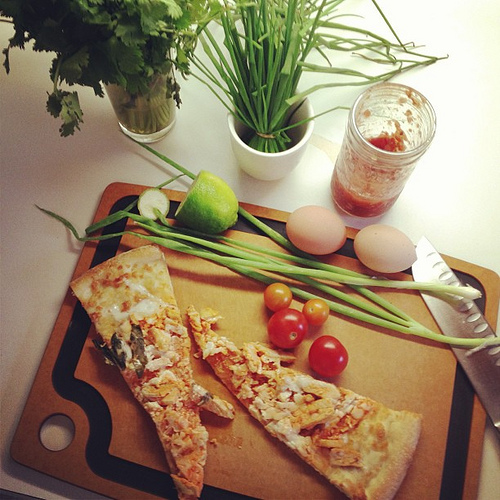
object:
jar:
[331, 79, 437, 222]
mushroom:
[110, 332, 135, 368]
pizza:
[67, 245, 210, 499]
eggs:
[285, 203, 348, 254]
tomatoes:
[269, 306, 309, 349]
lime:
[171, 168, 241, 237]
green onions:
[452, 282, 479, 300]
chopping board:
[11, 182, 499, 499]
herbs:
[45, 72, 83, 138]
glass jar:
[104, 56, 179, 145]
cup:
[226, 86, 314, 183]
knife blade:
[411, 234, 499, 429]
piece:
[137, 190, 170, 223]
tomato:
[307, 334, 349, 380]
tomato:
[264, 280, 292, 312]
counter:
[0, 0, 500, 499]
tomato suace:
[331, 128, 405, 218]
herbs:
[188, 72, 247, 124]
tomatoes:
[302, 297, 330, 327]